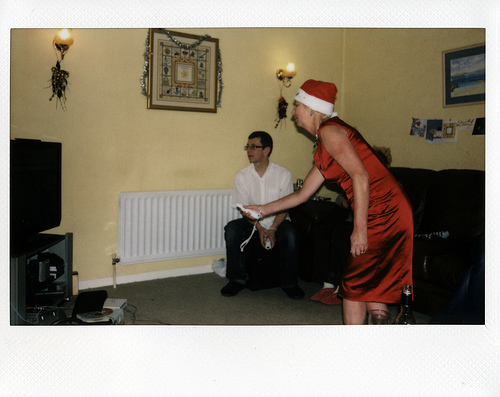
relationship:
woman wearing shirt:
[235, 78, 415, 326] [310, 114, 415, 301]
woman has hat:
[235, 78, 415, 326] [294, 78, 339, 114]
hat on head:
[294, 78, 339, 114] [292, 78, 338, 137]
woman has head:
[235, 78, 415, 326] [292, 78, 338, 137]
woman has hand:
[235, 78, 415, 326] [237, 200, 265, 220]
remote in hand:
[233, 200, 260, 251] [237, 200, 265, 220]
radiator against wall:
[118, 191, 242, 260] [11, 26, 326, 290]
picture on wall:
[148, 27, 217, 113] [11, 26, 326, 290]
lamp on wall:
[52, 27, 75, 63] [11, 26, 326, 290]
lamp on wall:
[276, 59, 297, 88] [11, 26, 326, 290]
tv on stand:
[11, 137, 67, 257] [12, 232, 75, 322]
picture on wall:
[444, 42, 491, 104] [343, 26, 485, 171]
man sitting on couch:
[221, 130, 304, 299] [246, 167, 484, 318]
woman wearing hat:
[235, 78, 415, 326] [294, 78, 339, 114]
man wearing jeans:
[221, 130, 304, 299] [224, 215, 299, 283]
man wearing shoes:
[221, 130, 304, 299] [220, 278, 306, 301]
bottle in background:
[398, 282, 415, 324] [401, 29, 485, 323]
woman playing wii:
[235, 78, 415, 326] [105, 293, 137, 325]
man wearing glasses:
[221, 130, 304, 299] [244, 141, 267, 152]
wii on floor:
[105, 293, 137, 325] [71, 272, 485, 324]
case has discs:
[73, 288, 114, 326] [79, 306, 115, 319]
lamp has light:
[52, 27, 75, 63] [55, 26, 72, 40]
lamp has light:
[276, 59, 297, 88] [287, 59, 293, 70]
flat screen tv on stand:
[11, 137, 67, 257] [12, 232, 75, 322]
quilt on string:
[45, 62, 69, 113] [53, 38, 64, 61]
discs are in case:
[79, 306, 115, 319] [73, 288, 114, 326]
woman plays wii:
[235, 78, 415, 326] [105, 293, 137, 325]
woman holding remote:
[235, 78, 415, 326] [233, 200, 260, 251]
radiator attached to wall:
[118, 191, 242, 260] [11, 26, 326, 290]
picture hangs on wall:
[148, 27, 217, 113] [11, 26, 326, 290]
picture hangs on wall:
[444, 42, 491, 104] [343, 26, 485, 171]